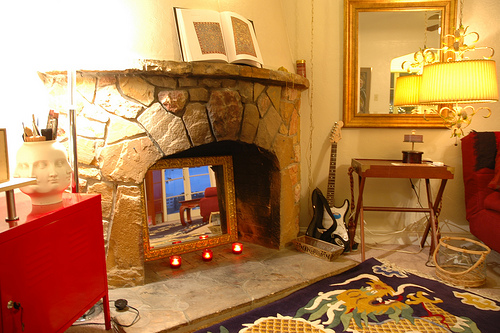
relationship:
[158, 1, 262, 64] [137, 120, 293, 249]
book atop fireplace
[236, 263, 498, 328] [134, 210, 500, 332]
carpet on floor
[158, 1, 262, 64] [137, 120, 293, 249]
book on fireplace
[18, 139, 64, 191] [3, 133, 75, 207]
face on vase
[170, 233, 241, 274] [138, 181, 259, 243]
candles near mirror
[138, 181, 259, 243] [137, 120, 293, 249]
mirror in fireplace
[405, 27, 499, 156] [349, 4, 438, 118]
light near mirror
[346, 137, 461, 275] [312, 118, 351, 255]
table near guitar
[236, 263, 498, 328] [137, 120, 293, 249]
carpet near fireplace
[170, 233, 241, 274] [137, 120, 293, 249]
candles near fireplace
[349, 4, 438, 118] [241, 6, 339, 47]
mirror placed on wall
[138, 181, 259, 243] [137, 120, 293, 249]
mirror inside fireplace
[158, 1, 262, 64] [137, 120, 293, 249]
book over fireplace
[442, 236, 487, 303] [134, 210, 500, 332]
basket sitting on floor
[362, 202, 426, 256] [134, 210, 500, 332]
wire on floor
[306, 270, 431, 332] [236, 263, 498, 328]
dragon on carpet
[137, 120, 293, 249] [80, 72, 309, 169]
fireplace made of stone